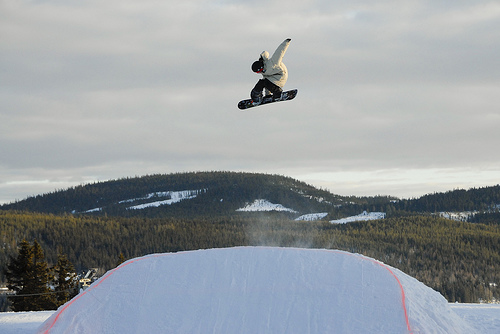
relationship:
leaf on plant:
[482, 246, 486, 251] [2, 209, 494, 305]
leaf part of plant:
[73, 216, 178, 248] [5, 209, 495, 255]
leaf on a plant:
[368, 225, 399, 237] [413, 232, 457, 262]